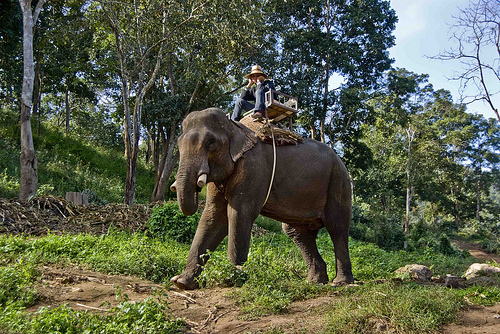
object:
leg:
[282, 222, 327, 274]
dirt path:
[0, 228, 499, 334]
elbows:
[264, 86, 272, 91]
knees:
[255, 89, 264, 94]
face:
[251, 73, 260, 82]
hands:
[257, 76, 265, 82]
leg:
[323, 212, 353, 276]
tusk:
[170, 173, 208, 192]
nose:
[176, 166, 198, 216]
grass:
[237, 281, 301, 312]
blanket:
[239, 116, 305, 147]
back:
[290, 138, 342, 157]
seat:
[239, 87, 306, 147]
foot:
[170, 272, 199, 289]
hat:
[245, 65, 268, 80]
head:
[251, 65, 262, 83]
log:
[390, 262, 500, 283]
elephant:
[170, 107, 352, 290]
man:
[231, 65, 278, 121]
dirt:
[59, 270, 166, 298]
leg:
[186, 196, 228, 269]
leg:
[227, 197, 265, 266]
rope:
[262, 126, 277, 207]